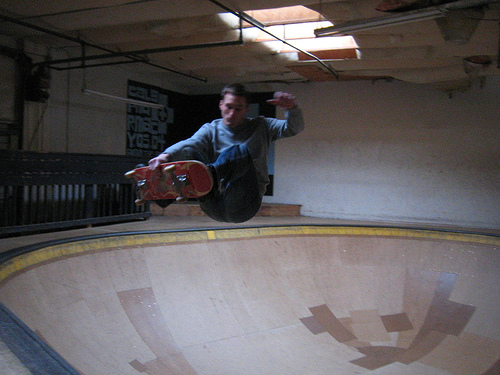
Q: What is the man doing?
A: A man doing a skateboard trick.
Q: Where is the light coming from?
A: Light from a ceiling window.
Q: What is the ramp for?
A: A skateboard ramp for tricks.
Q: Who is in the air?
A: A skateboarder in the air.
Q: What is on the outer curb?
A: A yellow line on outer curb.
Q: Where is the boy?
A: The inside of a skatepark.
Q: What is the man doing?
A: Man doing jump on skateboard.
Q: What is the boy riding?
A: Skateboard.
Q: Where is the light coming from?
A: Skylight.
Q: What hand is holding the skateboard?
A: Right.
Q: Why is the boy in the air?
A: He jumped.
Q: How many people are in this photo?
A: One.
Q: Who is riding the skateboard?
A: The boy.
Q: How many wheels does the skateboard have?
A: Four.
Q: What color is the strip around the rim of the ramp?
A: Yellow.